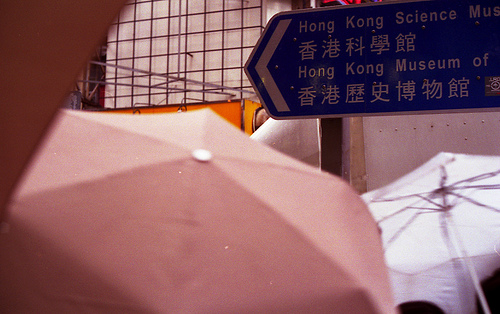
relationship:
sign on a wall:
[243, 8, 497, 122] [67, 2, 498, 202]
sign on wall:
[243, 0, 500, 120] [336, 107, 453, 185]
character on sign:
[295, 32, 318, 59] [247, 6, 499, 114]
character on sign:
[389, 79, 421, 109] [247, 6, 499, 114]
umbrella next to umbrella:
[328, 135, 499, 311] [26, 123, 273, 310]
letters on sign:
[291, 28, 470, 111] [243, 8, 497, 122]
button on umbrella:
[186, 144, 221, 168] [0, 88, 400, 310]